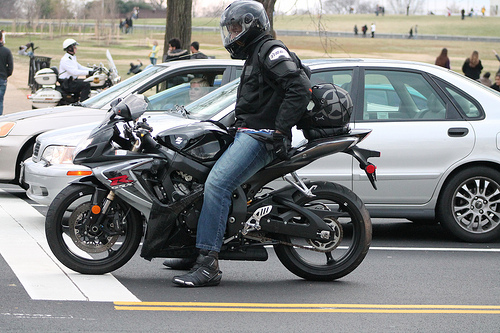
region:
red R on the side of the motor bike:
[104, 174, 136, 190]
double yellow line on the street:
[110, 292, 440, 319]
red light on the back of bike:
[360, 159, 380, 190]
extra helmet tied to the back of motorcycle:
[307, 84, 357, 148]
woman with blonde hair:
[185, 76, 225, 100]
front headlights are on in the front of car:
[35, 137, 83, 185]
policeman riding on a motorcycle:
[26, 38, 120, 103]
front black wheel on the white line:
[42, 179, 141, 300]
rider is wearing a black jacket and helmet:
[215, 0, 310, 135]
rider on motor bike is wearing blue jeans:
[195, 127, 284, 254]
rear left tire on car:
[442, 160, 497, 243]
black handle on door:
[443, 119, 475, 141]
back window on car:
[364, 68, 445, 128]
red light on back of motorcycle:
[361, 162, 376, 177]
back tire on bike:
[280, 181, 372, 285]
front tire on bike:
[44, 184, 142, 279]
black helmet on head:
[220, 3, 270, 57]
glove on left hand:
[271, 121, 286, 155]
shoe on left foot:
[175, 253, 221, 292]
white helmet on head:
[55, 32, 75, 47]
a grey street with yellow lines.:
[346, 277, 498, 332]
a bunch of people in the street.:
[339, 18, 429, 43]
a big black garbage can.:
[21, 50, 54, 91]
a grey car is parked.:
[318, 52, 499, 244]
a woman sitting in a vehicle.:
[163, 56, 235, 103]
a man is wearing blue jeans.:
[233, 139, 258, 174]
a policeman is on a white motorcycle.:
[22, 34, 125, 114]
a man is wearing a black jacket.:
[253, 65, 285, 107]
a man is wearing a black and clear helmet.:
[213, 1, 273, 61]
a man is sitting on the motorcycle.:
[40, 0, 382, 296]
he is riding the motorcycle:
[25, 0, 375, 287]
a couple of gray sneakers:
[165, 250, 224, 285]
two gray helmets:
[212, 5, 352, 128]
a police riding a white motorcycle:
[27, 38, 122, 108]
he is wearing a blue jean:
[193, 128, 275, 253]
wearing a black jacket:
[231, 43, 305, 134]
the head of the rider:
[220, 0, 271, 56]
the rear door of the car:
[357, 76, 472, 207]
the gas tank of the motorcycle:
[158, 123, 233, 161]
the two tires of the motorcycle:
[45, 183, 367, 279]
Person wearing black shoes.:
[162, 2, 313, 289]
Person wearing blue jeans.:
[163, 1, 311, 289]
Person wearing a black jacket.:
[163, 0, 314, 290]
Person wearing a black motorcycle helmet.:
[163, 0, 313, 291]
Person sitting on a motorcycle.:
[161, 2, 312, 289]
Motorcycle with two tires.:
[44, 89, 371, 281]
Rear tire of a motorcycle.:
[271, 181, 373, 280]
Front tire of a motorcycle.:
[43, 182, 141, 275]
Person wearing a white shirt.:
[57, 38, 98, 102]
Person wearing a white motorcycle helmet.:
[58, 37, 97, 102]